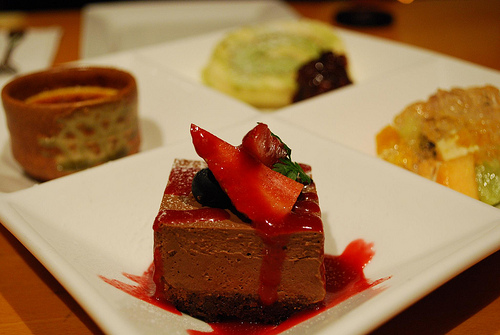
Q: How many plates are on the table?
A: Four.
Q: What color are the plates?
A: White.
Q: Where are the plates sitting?
A: Table.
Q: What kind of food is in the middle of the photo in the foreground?
A: Dessert.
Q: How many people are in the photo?
A: None.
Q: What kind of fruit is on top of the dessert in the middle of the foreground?
A: Strawberry.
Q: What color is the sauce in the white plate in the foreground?
A: Red.